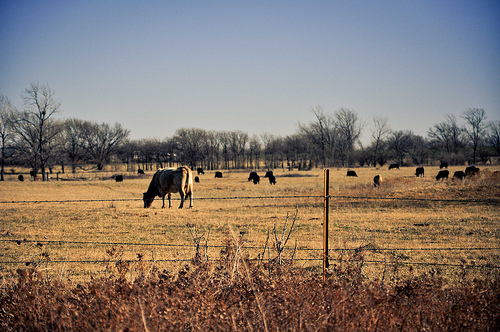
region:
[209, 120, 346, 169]
line of trees behind the cows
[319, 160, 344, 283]
pole holding the barbed wire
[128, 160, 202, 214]
cow grazing on the dead grass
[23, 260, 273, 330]
dead weeds by the fence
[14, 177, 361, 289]
barbed wire fence surrounding the field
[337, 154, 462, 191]
cows grazing in the field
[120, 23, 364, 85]
hazy blue grey sky above the field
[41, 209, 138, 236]
brown grass in the field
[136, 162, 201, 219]
cow standing by itself in the field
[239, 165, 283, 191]
black cows together in the field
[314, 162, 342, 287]
metal pole with barbed wire attached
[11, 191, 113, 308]
barbed wire fence around the field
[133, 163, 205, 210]
cow eating the dry grass on the ground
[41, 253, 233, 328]
dry dead weeds by the fence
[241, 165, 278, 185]
black cows in the distance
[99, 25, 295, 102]
hazy blue grey sky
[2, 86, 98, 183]
trees with no leaves on branches in the background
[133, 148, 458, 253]
field of cows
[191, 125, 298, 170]
row of trees behind the cows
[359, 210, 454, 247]
yellow grass in the field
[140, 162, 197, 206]
this is a cow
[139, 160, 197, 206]
the cow is feeding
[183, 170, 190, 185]
this is the tail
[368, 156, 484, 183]
the herd of cattle is feeding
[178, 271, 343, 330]
the grass is brown in color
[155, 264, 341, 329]
the grass is dry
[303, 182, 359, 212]
this is a fence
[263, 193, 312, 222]
the grass is dry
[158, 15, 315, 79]
the sky is grey in color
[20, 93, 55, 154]
the trees are dry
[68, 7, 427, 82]
this is the sky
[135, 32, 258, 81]
the sky is blue in color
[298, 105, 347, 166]
this is a tree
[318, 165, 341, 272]
this is a pole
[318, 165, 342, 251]
the pole is metallic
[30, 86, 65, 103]
the leaves are green inn color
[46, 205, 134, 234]
this is a grass area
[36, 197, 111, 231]
the grass is green in color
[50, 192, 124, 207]
this is a wire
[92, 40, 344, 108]
Sky is blue color.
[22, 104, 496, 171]
Trees are without leaves.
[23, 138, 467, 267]
Animals are in ground.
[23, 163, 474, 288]
Wire fence is in ground.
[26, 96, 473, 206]
trees are behind the animals.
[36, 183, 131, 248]
Grass is brown color.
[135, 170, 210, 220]
Cow is brown and white color.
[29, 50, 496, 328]
Day time picture.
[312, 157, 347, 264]
Pole is yellow color.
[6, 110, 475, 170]
woods are brown color.